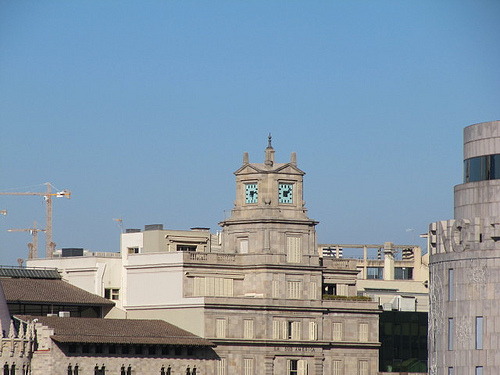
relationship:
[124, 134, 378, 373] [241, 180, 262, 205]
building has a clock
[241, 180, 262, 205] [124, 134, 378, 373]
clock on building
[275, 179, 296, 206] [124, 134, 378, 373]
clock on building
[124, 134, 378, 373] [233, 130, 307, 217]
building has a tower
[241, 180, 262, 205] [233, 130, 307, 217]
clock on tower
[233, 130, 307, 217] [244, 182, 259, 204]
tower has clock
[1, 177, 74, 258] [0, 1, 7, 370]
crane on left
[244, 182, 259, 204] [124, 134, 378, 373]
clock are on building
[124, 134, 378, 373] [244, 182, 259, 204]
building has clock